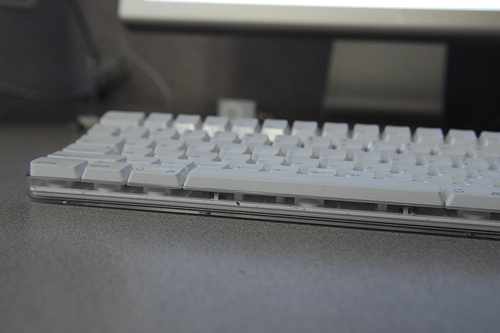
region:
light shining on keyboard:
[165, 115, 290, 135]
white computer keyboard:
[42, 105, 409, 208]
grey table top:
[39, 225, 275, 320]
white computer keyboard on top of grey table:
[35, 89, 485, 274]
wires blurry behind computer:
[17, 10, 145, 129]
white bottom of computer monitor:
[115, 10, 498, 42]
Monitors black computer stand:
[208, 40, 494, 115]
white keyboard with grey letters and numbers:
[45, 98, 237, 214]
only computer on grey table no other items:
[21, 20, 497, 293]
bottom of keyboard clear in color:
[29, 175, 494, 225]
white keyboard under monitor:
[27, 6, 495, 246]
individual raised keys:
[35, 95, 495, 210]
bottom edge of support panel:
[25, 176, 492, 242]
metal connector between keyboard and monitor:
[311, 25, 456, 137]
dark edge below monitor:
[117, 1, 492, 43]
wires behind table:
[67, 1, 177, 126]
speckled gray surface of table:
[2, 117, 487, 323]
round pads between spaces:
[30, 171, 490, 221]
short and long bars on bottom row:
[30, 146, 495, 216]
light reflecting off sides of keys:
[175, 113, 286, 139]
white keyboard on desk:
[21, 88, 491, 228]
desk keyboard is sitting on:
[5, 108, 494, 331]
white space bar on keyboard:
[183, 162, 436, 212]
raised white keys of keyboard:
[29, 79, 486, 208]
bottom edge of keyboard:
[27, 178, 495, 243]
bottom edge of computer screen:
[112, 3, 484, 40]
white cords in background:
[62, 28, 178, 120]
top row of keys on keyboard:
[100, 100, 498, 146]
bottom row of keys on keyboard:
[23, 159, 499, 219]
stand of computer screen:
[427, 45, 499, 115]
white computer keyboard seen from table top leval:
[26, 108, 496, 233]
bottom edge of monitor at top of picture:
[120, 2, 497, 42]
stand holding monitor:
[315, 37, 450, 127]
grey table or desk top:
[5, 130, 495, 330]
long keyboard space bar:
[185, 161, 440, 208]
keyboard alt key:
[128, 160, 179, 195]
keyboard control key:
[30, 155, 81, 180]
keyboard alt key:
[442, 188, 497, 213]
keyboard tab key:
[77, 130, 120, 150]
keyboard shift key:
[75, 140, 113, 160]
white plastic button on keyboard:
[95, 105, 483, 232]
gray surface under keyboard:
[34, 186, 330, 329]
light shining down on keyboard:
[168, 82, 312, 145]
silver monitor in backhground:
[133, 12, 496, 109]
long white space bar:
[192, 164, 434, 218]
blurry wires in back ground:
[97, 30, 220, 120]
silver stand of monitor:
[316, 27, 480, 124]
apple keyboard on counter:
[112, 93, 497, 288]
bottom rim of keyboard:
[48, 175, 492, 225]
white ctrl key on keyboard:
[37, 150, 79, 190]